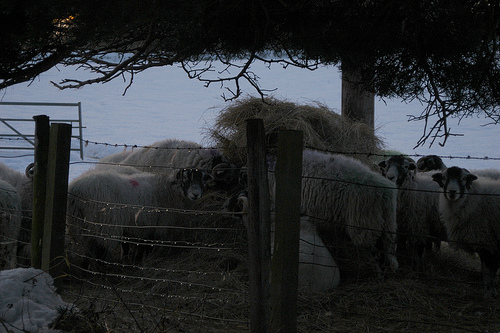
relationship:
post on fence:
[41, 115, 75, 278] [17, 142, 492, 324]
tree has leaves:
[57, 2, 499, 155] [54, 1, 499, 119]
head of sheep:
[369, 145, 413, 190] [383, 149, 451, 231]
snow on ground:
[1, 57, 498, 182] [2, 54, 475, 186]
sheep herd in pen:
[3, 121, 498, 302] [1, 90, 498, 331]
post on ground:
[244, 116, 276, 321] [53, 253, 496, 330]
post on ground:
[270, 127, 302, 323] [53, 253, 496, 330]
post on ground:
[265, 127, 303, 332] [53, 253, 496, 330]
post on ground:
[28, 112, 50, 269] [53, 253, 496, 330]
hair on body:
[314, 167, 364, 205] [237, 143, 484, 320]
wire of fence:
[311, 140, 498, 166] [19, 113, 302, 333]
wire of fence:
[313, 175, 494, 200] [19, 113, 302, 333]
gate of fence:
[0, 99, 92, 171] [2, 117, 499, 331]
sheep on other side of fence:
[7, 120, 499, 327] [2, 117, 499, 331]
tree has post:
[0, 0, 498, 155] [328, 47, 385, 177]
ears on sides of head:
[437, 173, 471, 178] [427, 165, 472, 202]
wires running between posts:
[71, 130, 236, 290] [6, 100, 311, 295]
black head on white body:
[167, 165, 203, 198] [77, 171, 164, 236]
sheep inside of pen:
[430, 165, 498, 287] [1, 98, 484, 320]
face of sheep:
[181, 167, 207, 201] [73, 162, 214, 266]